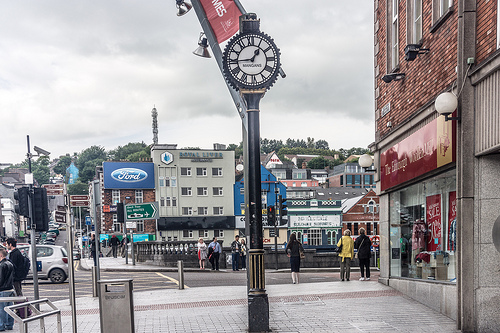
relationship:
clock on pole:
[223, 34, 288, 93] [216, 18, 300, 332]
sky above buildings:
[0, 5, 381, 152] [77, 131, 378, 259]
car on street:
[9, 239, 72, 285] [25, 260, 399, 307]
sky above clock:
[0, 5, 381, 152] [223, 34, 288, 93]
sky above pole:
[0, 5, 381, 152] [216, 18, 300, 332]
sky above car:
[0, 5, 381, 152] [9, 239, 72, 285]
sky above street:
[0, 5, 381, 152] [25, 260, 399, 307]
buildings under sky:
[77, 131, 378, 259] [0, 5, 381, 152]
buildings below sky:
[77, 131, 378, 259] [0, 5, 381, 152]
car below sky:
[9, 239, 72, 285] [0, 5, 381, 152]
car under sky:
[9, 239, 72, 285] [0, 5, 381, 152]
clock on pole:
[217, 29, 286, 87] [216, 18, 300, 332]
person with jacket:
[327, 228, 361, 283] [330, 233, 358, 261]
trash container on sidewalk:
[93, 277, 135, 331] [38, 274, 458, 331]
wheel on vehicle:
[45, 264, 70, 286] [3, 241, 71, 286]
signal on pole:
[7, 182, 56, 237] [25, 229, 42, 316]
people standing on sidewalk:
[283, 225, 375, 285] [14, 282, 465, 331]